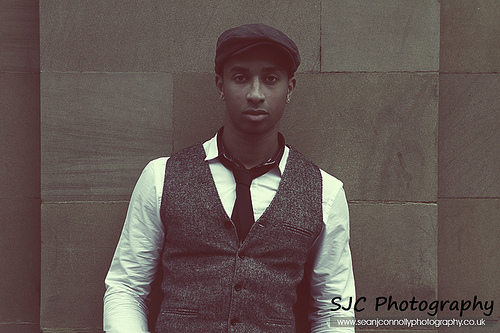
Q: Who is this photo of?
A: A clean shaven man.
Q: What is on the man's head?
A: A hat.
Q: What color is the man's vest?
A: Gray.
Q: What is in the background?
A: A wall.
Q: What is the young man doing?
A: Leaning against wall.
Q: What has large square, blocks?
A: The wall behind a young man.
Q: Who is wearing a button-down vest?
A: A man with a black tie, loosened at the neck.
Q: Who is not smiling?
A: A man with a white, collared shirt and vest.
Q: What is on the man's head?
A: A cap.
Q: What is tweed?
A: The man's vest.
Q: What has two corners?
A: The wall, backing the man.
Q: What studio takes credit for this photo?
A: SJC Photography.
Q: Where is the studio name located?
A: On the right, bottom corner.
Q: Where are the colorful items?
A: There are none.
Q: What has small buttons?
A: A vest, on a man.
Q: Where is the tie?
A: Around the man's neck.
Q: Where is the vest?
A: Over the white shirt.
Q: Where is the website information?
A: Bottom right.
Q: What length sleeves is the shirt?
A: Long.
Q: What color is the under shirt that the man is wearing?
A: The under shirt is white.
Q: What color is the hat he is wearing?
A: The hat is black.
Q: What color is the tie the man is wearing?
A: The tie is black.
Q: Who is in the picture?
A: A young man is in the picture.